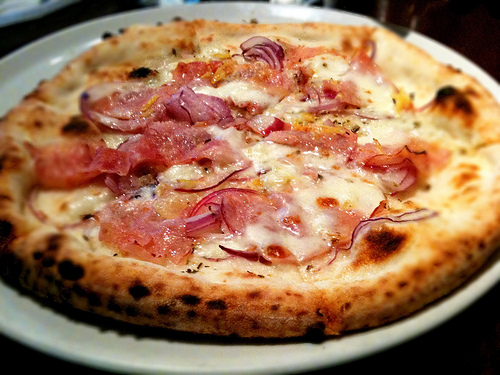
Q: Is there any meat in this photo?
A: Yes, there is meat.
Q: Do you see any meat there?
A: Yes, there is meat.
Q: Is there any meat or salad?
A: Yes, there is meat.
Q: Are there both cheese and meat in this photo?
A: Yes, there are both meat and cheese.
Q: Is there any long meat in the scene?
A: Yes, there is long meat.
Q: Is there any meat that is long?
A: Yes, there is meat that is long.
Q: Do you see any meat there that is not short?
A: Yes, there is long meat.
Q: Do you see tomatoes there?
A: No, there are no tomatoes.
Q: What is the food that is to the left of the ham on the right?
A: The food is meat.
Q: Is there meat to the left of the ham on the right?
A: Yes, there is meat to the left of the ham.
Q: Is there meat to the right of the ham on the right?
A: No, the meat is to the left of the ham.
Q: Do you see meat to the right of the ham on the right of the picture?
A: No, the meat is to the left of the ham.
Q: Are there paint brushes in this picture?
A: No, there are no paint brushes.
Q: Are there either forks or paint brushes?
A: No, there are no paint brushes or forks.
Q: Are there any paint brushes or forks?
A: No, there are no paint brushes or forks.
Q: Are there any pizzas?
A: Yes, there is a pizza.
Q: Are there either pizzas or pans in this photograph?
A: Yes, there is a pizza.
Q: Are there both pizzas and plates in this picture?
A: Yes, there are both a pizza and a plate.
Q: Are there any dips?
A: No, there are no dips.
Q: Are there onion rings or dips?
A: No, there are no dips or onion rings.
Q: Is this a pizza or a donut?
A: This is a pizza.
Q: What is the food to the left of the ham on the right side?
A: The food is a pizza.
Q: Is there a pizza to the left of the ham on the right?
A: Yes, there is a pizza to the left of the ham.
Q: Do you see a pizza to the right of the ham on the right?
A: No, the pizza is to the left of the ham.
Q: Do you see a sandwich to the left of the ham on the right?
A: No, there is a pizza to the left of the ham.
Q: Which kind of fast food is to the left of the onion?
A: The food is a pizza.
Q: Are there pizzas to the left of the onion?
A: Yes, there is a pizza to the left of the onion.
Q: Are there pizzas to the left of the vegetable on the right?
A: Yes, there is a pizza to the left of the onion.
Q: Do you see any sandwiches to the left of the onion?
A: No, there is a pizza to the left of the onion.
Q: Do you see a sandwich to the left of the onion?
A: No, there is a pizza to the left of the onion.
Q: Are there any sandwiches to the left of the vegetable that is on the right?
A: No, there is a pizza to the left of the onion.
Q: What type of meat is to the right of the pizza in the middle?
A: The meat is ham.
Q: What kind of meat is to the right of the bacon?
A: The meat is ham.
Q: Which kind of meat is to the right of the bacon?
A: The meat is ham.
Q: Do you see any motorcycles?
A: No, there are no motorcycles.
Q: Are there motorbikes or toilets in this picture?
A: No, there are no motorbikes or toilets.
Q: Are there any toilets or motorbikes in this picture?
A: No, there are no motorbikes or toilets.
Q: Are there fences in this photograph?
A: No, there are no fences.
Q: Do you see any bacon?
A: Yes, there is bacon.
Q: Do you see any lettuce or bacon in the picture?
A: Yes, there is bacon.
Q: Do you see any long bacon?
A: Yes, there is long bacon.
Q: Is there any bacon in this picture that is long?
A: Yes, there is bacon that is long.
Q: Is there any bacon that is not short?
A: Yes, there is long bacon.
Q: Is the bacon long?
A: Yes, the bacon is long.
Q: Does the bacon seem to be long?
A: Yes, the bacon is long.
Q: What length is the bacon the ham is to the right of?
A: The bacon is long.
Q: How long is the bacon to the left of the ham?
A: The bacon is long.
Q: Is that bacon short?
A: No, the bacon is long.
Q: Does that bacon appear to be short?
A: No, the bacon is long.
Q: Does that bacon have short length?
A: No, the bacon is long.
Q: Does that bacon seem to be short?
A: No, the bacon is long.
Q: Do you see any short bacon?
A: No, there is bacon but it is long.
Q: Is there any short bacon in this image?
A: No, there is bacon but it is long.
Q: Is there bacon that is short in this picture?
A: No, there is bacon but it is long.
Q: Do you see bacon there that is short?
A: No, there is bacon but it is long.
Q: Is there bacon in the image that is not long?
A: No, there is bacon but it is long.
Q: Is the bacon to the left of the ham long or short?
A: The bacon is long.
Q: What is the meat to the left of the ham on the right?
A: The meat is bacon.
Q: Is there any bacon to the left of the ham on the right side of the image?
A: Yes, there is bacon to the left of the ham.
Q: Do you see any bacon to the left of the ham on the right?
A: Yes, there is bacon to the left of the ham.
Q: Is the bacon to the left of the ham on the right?
A: Yes, the bacon is to the left of the ham.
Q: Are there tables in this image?
A: Yes, there is a table.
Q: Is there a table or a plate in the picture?
A: Yes, there is a table.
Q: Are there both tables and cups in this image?
A: No, there is a table but no cups.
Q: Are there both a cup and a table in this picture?
A: No, there is a table but no cups.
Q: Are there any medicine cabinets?
A: No, there are no medicine cabinets.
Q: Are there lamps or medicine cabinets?
A: No, there are no medicine cabinets or lamps.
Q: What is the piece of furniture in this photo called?
A: The piece of furniture is a table.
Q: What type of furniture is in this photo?
A: The furniture is a table.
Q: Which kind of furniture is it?
A: The piece of furniture is a table.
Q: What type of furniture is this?
A: This is a table.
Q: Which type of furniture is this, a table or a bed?
A: This is a table.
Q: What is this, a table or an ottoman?
A: This is a table.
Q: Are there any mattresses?
A: No, there are no mattresses.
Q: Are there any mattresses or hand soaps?
A: No, there are no mattresses or hand soaps.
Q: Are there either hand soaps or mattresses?
A: No, there are no mattresses or hand soaps.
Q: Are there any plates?
A: Yes, there is a plate.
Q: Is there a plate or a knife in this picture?
A: Yes, there is a plate.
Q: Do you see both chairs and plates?
A: No, there is a plate but no chairs.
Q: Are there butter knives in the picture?
A: No, there are no butter knives.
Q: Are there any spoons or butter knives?
A: No, there are no butter knives or spoons.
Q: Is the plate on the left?
A: Yes, the plate is on the left of the image.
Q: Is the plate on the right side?
A: No, the plate is on the left of the image.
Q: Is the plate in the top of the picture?
A: No, the plate is in the bottom of the image.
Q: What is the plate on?
A: The plate is on the counter.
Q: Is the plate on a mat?
A: No, the plate is on a counter.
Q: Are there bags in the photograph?
A: No, there are no bags.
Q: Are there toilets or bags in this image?
A: No, there are no bags or toilets.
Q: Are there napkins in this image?
A: No, there are no napkins.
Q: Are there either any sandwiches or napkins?
A: No, there are no napkins or sandwiches.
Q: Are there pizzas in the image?
A: Yes, there is a pizza.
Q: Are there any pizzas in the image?
A: Yes, there is a pizza.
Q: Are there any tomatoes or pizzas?
A: Yes, there is a pizza.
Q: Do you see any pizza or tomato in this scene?
A: Yes, there is a pizza.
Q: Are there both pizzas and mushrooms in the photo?
A: No, there is a pizza but no mushrooms.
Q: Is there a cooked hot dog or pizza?
A: Yes, there is a cooked pizza.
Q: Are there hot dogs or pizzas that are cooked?
A: Yes, the pizza is cooked.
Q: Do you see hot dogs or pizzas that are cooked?
A: Yes, the pizza is cooked.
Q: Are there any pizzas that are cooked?
A: Yes, there is a cooked pizza.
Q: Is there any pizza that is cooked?
A: Yes, there is a pizza that is cooked.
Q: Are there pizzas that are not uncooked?
A: Yes, there is an cooked pizza.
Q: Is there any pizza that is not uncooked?
A: Yes, there is an cooked pizza.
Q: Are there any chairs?
A: No, there are no chairs.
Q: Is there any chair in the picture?
A: No, there are no chairs.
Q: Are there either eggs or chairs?
A: No, there are no chairs or eggs.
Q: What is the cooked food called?
A: The food is a pizza.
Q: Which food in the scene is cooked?
A: The food is a pizza.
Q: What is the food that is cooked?
A: The food is a pizza.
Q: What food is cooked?
A: The food is a pizza.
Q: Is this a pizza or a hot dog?
A: This is a pizza.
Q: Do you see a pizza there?
A: Yes, there is a pizza.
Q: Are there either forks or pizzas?
A: Yes, there is a pizza.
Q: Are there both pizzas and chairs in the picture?
A: No, there is a pizza but no chairs.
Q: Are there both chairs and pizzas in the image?
A: No, there is a pizza but no chairs.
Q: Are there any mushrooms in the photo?
A: No, there are no mushrooms.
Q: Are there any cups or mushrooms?
A: No, there are no mushrooms or cups.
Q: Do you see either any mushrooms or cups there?
A: No, there are no mushrooms or cups.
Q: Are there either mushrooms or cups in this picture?
A: No, there are no mushrooms or cups.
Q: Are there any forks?
A: No, there are no forks.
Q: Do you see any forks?
A: No, there are no forks.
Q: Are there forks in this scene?
A: No, there are no forks.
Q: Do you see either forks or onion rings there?
A: No, there are no forks or onion rings.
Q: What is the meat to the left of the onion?
A: The meat is ham.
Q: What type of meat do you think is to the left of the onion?
A: The meat is ham.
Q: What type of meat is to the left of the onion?
A: The meat is ham.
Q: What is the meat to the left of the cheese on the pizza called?
A: The meat is ham.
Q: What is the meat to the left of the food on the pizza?
A: The meat is ham.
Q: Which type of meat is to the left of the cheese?
A: The meat is ham.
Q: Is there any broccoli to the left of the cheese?
A: No, there is ham to the left of the cheese.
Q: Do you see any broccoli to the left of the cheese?
A: No, there is ham to the left of the cheese.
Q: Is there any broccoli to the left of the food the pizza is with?
A: No, there is ham to the left of the cheese.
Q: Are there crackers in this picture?
A: No, there are no crackers.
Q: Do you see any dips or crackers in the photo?
A: No, there are no crackers or dips.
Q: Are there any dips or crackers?
A: No, there are no crackers or dips.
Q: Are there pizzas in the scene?
A: Yes, there is a pizza.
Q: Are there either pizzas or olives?
A: Yes, there is a pizza.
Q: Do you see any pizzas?
A: Yes, there is a pizza.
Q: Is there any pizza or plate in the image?
A: Yes, there is a pizza.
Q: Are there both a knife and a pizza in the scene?
A: No, there is a pizza but no knives.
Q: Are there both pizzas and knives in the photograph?
A: No, there is a pizza but no knives.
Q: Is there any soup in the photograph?
A: No, there is no soup.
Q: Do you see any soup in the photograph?
A: No, there is no soup.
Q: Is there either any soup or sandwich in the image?
A: No, there are no soup or sandwiches.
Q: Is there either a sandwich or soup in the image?
A: No, there are no soup or sandwiches.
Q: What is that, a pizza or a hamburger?
A: That is a pizza.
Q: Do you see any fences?
A: No, there are no fences.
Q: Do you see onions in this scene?
A: Yes, there is an onion.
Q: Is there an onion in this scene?
A: Yes, there is an onion.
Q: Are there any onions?
A: Yes, there is an onion.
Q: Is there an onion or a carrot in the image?
A: Yes, there is an onion.